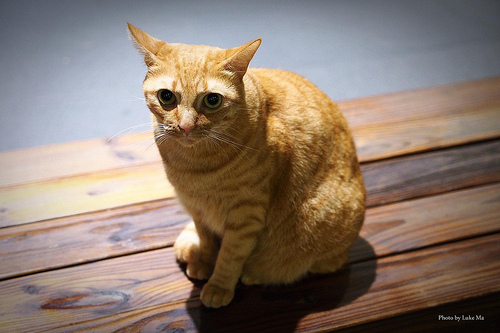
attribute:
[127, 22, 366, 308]
cat — yellow, tiger cat, sitting, orange striped, nervous, looking, sitted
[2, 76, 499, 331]
bench — wood, wooden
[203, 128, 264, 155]
whisker — white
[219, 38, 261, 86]
ear — pointed, apart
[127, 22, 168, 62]
ear — pointed, apart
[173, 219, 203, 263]
tail — curled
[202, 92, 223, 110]
eye — large, light colored, dark, wide open, big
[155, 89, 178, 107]
eye — dark, wide open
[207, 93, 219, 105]
pupil — large, dilated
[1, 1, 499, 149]
wall — blue, grey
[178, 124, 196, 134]
nose — pink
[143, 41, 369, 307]
fur — striped, white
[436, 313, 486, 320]
writing — water mark, logo, white